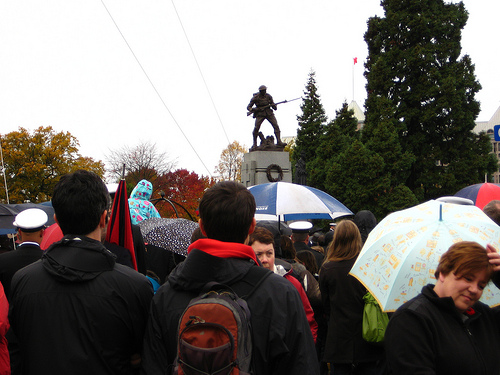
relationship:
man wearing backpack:
[147, 181, 323, 374] [172, 260, 276, 374]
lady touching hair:
[382, 239, 498, 373] [435, 240, 496, 284]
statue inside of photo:
[245, 83, 305, 151] [2, 1, 499, 371]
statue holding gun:
[245, 83, 305, 151] [246, 94, 306, 119]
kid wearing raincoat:
[127, 178, 163, 227] [128, 177, 162, 227]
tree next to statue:
[291, 65, 328, 191] [245, 83, 305, 151]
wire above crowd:
[95, 1, 212, 175] [0, 174, 499, 373]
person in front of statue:
[327, 219, 338, 239] [245, 83, 305, 151]